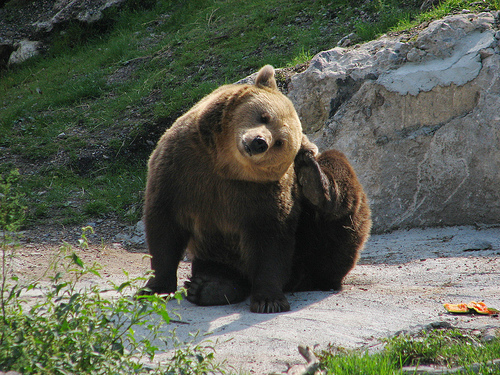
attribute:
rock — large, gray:
[286, 60, 468, 171]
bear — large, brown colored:
[190, 67, 431, 305]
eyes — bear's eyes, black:
[247, 104, 290, 154]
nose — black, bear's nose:
[247, 132, 270, 160]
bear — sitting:
[139, 59, 321, 314]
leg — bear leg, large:
[184, 231, 250, 309]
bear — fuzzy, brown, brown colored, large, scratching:
[139, 67, 371, 315]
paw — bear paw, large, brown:
[247, 289, 291, 319]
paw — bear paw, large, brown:
[137, 275, 176, 295]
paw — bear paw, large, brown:
[187, 269, 247, 314]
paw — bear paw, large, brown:
[294, 153, 339, 213]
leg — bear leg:
[137, 178, 195, 299]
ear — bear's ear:
[253, 58, 280, 87]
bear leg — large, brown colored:
[298, 152, 378, 279]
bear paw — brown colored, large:
[134, 275, 179, 296]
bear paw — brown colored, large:
[182, 268, 244, 305]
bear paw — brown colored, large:
[244, 274, 293, 314]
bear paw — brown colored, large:
[292, 149, 331, 210]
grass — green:
[75, 48, 129, 69]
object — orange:
[415, 277, 498, 319]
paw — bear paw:
[242, 287, 314, 345]